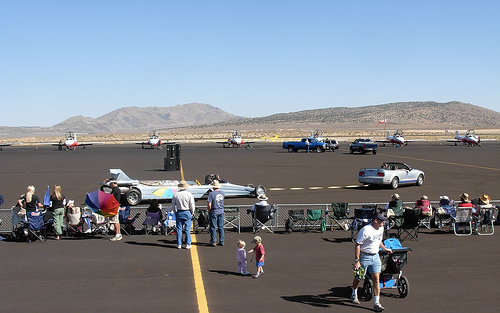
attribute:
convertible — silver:
[342, 151, 442, 196]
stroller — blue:
[360, 233, 420, 300]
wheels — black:
[361, 276, 416, 299]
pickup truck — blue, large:
[283, 137, 329, 155]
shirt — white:
[343, 232, 402, 267]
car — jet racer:
[103, 168, 258, 198]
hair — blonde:
[234, 235, 246, 247]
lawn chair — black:
[285, 207, 305, 229]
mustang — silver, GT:
[351, 162, 425, 189]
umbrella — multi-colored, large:
[83, 187, 118, 218]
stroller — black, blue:
[369, 236, 414, 298]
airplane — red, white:
[387, 130, 408, 149]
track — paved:
[5, 139, 499, 306]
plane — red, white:
[55, 130, 106, 156]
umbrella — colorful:
[76, 184, 128, 237]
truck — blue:
[283, 138, 332, 150]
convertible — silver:
[348, 150, 430, 207]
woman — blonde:
[50, 186, 68, 239]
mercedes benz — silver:
[359, 154, 426, 186]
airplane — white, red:
[213, 125, 259, 153]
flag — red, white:
[376, 115, 388, 125]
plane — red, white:
[214, 122, 266, 150]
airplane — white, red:
[130, 132, 180, 150]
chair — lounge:
[473, 206, 497, 234]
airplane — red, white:
[50, 134, 92, 152]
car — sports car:
[354, 158, 428, 193]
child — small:
[247, 233, 269, 281]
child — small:
[230, 237, 250, 277]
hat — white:
[171, 178, 192, 191]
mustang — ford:
[360, 160, 429, 184]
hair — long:
[54, 183, 64, 202]